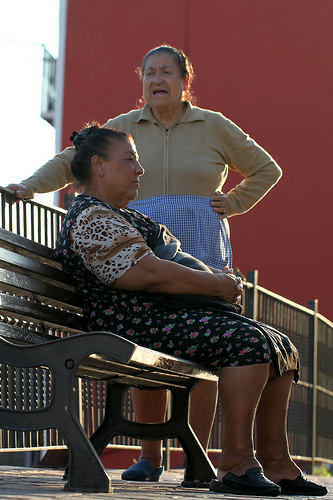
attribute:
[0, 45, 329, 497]
women — old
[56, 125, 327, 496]
woman — sitting, old, waiting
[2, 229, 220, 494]
bench — wooden, iron, black, wood, metal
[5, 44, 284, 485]
woman — yelling, standing, old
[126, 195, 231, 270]
apron — checkered, blue, white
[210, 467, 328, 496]
shoes — black, dark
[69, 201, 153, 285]
shirt — spotted, leopard print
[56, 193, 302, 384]
dress — black, flowered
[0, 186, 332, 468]
fence — black, metal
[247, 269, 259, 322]
post — metal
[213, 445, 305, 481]
ankles — swollen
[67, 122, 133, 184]
hair — up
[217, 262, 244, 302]
hands — folded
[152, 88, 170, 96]
mouth — open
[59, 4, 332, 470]
wall — red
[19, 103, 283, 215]
top — cream colored, zip-up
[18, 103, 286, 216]
dress — brown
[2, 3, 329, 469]
building — red